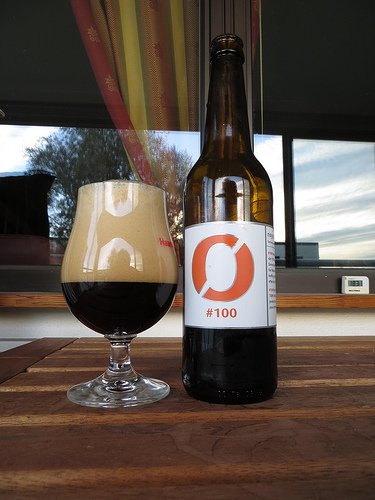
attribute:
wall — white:
[0, 309, 372, 340]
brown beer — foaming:
[62, 283, 171, 331]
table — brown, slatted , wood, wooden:
[0, 335, 374, 496]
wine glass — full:
[62, 187, 177, 420]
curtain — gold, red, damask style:
[74, 8, 209, 171]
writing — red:
[145, 231, 176, 249]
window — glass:
[254, 3, 374, 263]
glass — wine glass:
[198, 41, 288, 337]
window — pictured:
[1, 124, 288, 266]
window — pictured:
[291, 136, 374, 266]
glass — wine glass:
[59, 177, 176, 411]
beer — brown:
[61, 285, 181, 341]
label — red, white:
[179, 222, 286, 331]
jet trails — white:
[254, 138, 373, 264]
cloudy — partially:
[293, 142, 374, 254]